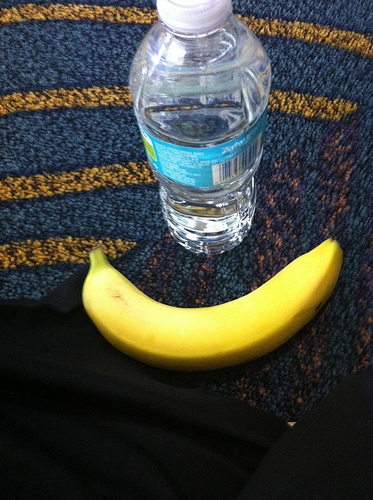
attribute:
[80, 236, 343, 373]
banana — healthy, ripe, yellow, long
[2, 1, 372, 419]
carpet — blue, yellow, colorful, here, multi colored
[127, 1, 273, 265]
bottle — water, unopened, plastic, clear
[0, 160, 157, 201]
stripe — yellow, gold, black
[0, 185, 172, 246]
stripe — blue, yarn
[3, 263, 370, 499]
material — black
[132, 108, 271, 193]
label — blue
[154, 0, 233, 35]
cap — white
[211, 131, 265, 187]
barcode — white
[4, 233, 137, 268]
stripe — yellow